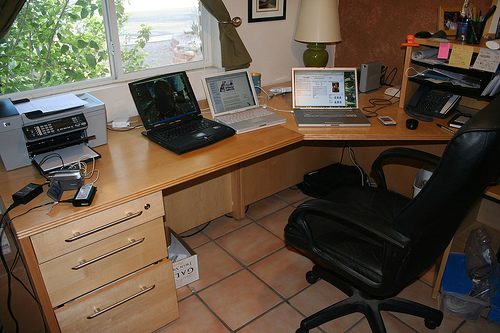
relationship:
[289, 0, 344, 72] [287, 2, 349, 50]
lamp with shade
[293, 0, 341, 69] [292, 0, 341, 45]
lamp with white shade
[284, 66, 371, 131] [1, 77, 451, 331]
computer on a desk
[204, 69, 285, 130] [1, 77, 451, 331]
computer on a desk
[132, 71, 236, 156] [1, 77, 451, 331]
computer on a desk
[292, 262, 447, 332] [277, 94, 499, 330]
base for chair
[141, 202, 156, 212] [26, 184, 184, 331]
lock for drawers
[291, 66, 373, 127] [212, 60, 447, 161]
computer on table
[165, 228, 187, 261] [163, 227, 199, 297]
trash in cardboard box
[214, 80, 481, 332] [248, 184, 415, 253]
chair has arms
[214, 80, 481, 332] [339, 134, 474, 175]
chair has arms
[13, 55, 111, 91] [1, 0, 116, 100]
bush outside window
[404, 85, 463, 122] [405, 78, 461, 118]
phone on desk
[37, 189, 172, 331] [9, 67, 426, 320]
drawers on desk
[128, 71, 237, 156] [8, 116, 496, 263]
computer on table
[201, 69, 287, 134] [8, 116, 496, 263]
computer on table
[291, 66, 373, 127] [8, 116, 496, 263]
computer on table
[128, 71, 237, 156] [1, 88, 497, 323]
computer on desk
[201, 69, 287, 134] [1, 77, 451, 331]
computer on desk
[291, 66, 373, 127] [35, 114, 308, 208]
computer on desk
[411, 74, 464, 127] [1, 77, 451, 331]
phone on desk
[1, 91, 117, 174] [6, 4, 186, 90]
printer under window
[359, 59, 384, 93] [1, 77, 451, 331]
modem on desk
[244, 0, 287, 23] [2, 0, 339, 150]
picture on wall